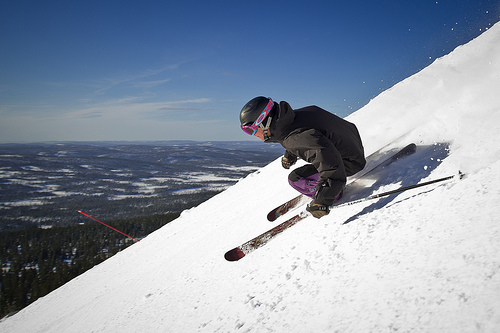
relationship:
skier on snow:
[223, 89, 365, 226] [10, 25, 498, 331]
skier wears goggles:
[223, 89, 365, 226] [240, 97, 278, 141]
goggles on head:
[240, 97, 278, 141] [231, 89, 289, 145]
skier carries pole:
[223, 89, 365, 226] [307, 172, 466, 204]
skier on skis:
[223, 89, 365, 226] [220, 143, 431, 262]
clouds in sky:
[64, 91, 215, 129] [3, 5, 493, 145]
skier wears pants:
[223, 89, 365, 226] [287, 166, 347, 208]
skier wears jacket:
[223, 89, 365, 226] [269, 101, 373, 201]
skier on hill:
[223, 89, 365, 226] [14, 77, 499, 314]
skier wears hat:
[223, 89, 365, 226] [242, 96, 277, 128]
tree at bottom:
[34, 248, 49, 272] [15, 295, 28, 298]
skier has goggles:
[223, 89, 365, 226] [240, 97, 278, 141]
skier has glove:
[223, 89, 365, 226] [305, 203, 336, 220]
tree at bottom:
[8, 255, 24, 276] [15, 295, 28, 298]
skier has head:
[223, 89, 365, 226] [231, 89, 289, 145]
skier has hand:
[223, 89, 365, 226] [281, 149, 298, 172]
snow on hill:
[10, 25, 498, 331] [14, 77, 499, 314]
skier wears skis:
[223, 89, 365, 226] [220, 143, 431, 262]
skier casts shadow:
[223, 89, 365, 226] [360, 145, 452, 217]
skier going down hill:
[223, 89, 365, 226] [14, 77, 499, 314]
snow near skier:
[10, 25, 498, 331] [223, 89, 365, 226]